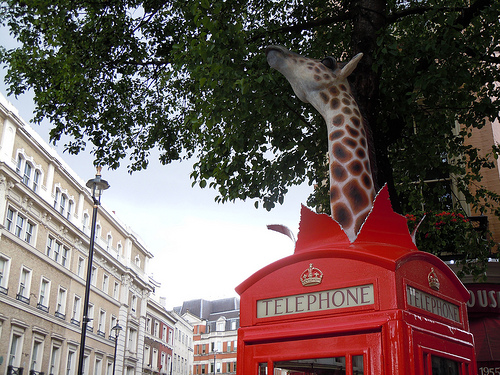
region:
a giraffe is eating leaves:
[201, 27, 482, 370]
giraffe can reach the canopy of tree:
[177, 22, 457, 257]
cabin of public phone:
[213, 184, 489, 374]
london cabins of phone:
[230, 184, 486, 371]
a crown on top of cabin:
[276, 255, 341, 295]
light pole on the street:
[61, 141, 117, 370]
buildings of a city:
[3, 97, 233, 374]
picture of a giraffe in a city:
[0, 2, 496, 373]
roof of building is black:
[162, 293, 239, 333]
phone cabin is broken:
[213, 169, 483, 374]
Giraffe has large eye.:
[312, 56, 334, 84]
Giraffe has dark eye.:
[313, 51, 358, 98]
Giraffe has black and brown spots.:
[343, 84, 372, 208]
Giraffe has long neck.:
[308, 99, 428, 233]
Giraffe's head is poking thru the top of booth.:
[291, 96, 420, 278]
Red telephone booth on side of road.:
[259, 228, 418, 342]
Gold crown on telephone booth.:
[290, 257, 339, 300]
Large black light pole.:
[67, 217, 143, 318]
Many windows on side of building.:
[33, 250, 127, 360]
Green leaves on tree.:
[176, 32, 264, 149]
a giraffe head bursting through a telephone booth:
[266, 34, 395, 238]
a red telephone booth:
[233, 241, 474, 372]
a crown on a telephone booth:
[295, 260, 332, 290]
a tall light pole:
[55, 145, 120, 370]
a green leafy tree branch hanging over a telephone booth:
[0, 0, 485, 180]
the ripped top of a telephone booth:
[260, 195, 435, 260]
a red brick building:
[187, 320, 237, 371]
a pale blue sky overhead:
[0, 1, 346, 298]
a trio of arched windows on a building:
[52, 183, 77, 220]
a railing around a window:
[34, 301, 51, 312]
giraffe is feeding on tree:
[243, 34, 383, 169]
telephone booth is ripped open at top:
[217, 186, 452, 288]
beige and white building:
[4, 105, 74, 373]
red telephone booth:
[206, 203, 469, 373]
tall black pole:
[72, 151, 106, 373]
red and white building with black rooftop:
[182, 296, 237, 373]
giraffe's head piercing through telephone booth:
[251, 30, 406, 264]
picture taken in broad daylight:
[5, 6, 325, 314]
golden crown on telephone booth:
[269, 247, 386, 297]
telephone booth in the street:
[205, 201, 482, 372]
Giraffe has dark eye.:
[321, 45, 338, 78]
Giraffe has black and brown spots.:
[319, 63, 368, 210]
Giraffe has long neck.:
[331, 90, 394, 202]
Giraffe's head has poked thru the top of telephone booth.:
[298, 172, 405, 277]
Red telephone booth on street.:
[284, 231, 416, 358]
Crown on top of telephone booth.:
[295, 254, 345, 311]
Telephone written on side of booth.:
[246, 291, 418, 314]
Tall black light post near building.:
[48, 170, 105, 360]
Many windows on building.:
[11, 193, 100, 350]